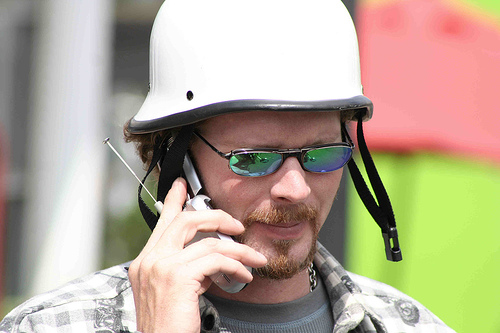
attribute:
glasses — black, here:
[193, 122, 356, 177]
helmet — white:
[126, 0, 373, 135]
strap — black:
[341, 116, 403, 262]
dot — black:
[187, 91, 194, 101]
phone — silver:
[102, 136, 253, 294]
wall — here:
[355, 0, 500, 161]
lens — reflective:
[303, 145, 354, 173]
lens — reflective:
[230, 151, 284, 177]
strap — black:
[138, 123, 196, 232]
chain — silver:
[309, 263, 318, 292]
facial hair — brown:
[235, 204, 317, 280]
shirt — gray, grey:
[0, 238, 457, 332]